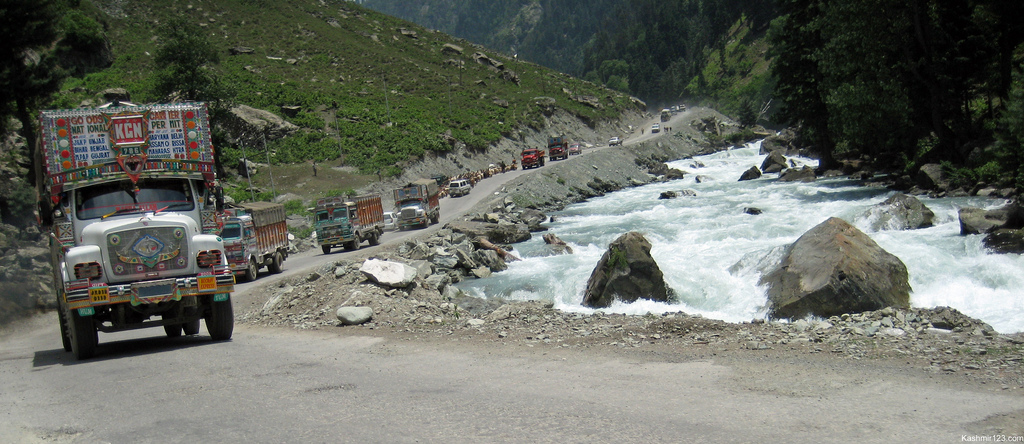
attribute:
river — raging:
[281, 203, 599, 256]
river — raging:
[502, 212, 652, 318]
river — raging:
[508, 190, 638, 303]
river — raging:
[469, 191, 686, 308]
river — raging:
[407, 136, 481, 258]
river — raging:
[543, 184, 716, 269]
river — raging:
[543, 117, 610, 245]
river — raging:
[554, 190, 660, 258]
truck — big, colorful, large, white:
[24, 85, 277, 395]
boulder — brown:
[760, 197, 929, 351]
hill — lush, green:
[175, 29, 469, 177]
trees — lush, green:
[711, 0, 1016, 234]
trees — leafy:
[656, 29, 1013, 244]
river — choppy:
[587, 124, 860, 375]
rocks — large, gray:
[723, 169, 952, 351]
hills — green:
[69, 22, 588, 241]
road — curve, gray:
[153, 156, 476, 440]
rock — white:
[337, 242, 454, 314]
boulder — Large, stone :
[743, 212, 942, 333]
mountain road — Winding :
[7, 88, 1017, 439]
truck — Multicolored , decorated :
[41, 116, 260, 384]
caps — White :
[557, 147, 998, 349]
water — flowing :
[497, 80, 1012, 372]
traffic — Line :
[7, 60, 703, 378]